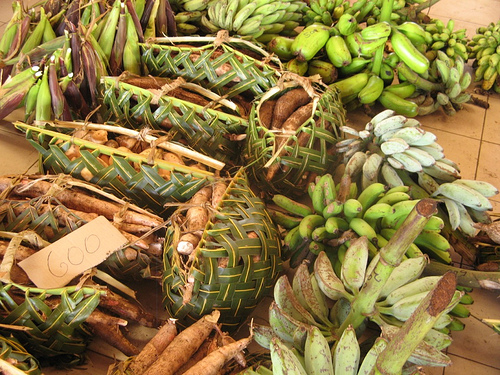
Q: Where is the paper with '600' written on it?
A: Lower left.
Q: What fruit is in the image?
A: Banana.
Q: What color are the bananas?
A: Green.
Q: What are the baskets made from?
A: Leaves.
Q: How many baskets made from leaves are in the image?
A: Seven.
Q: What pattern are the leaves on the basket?
A: Woven.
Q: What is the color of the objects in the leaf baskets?
A: Brown.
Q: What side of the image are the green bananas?
A: Right.